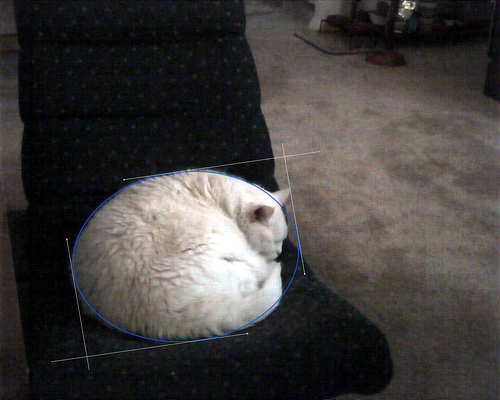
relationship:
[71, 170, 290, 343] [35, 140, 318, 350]
blue circle around cat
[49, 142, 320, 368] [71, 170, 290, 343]
lines drawn around blue circle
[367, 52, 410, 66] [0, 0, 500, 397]
dish on floor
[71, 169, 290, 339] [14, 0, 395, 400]
cat laying on black chair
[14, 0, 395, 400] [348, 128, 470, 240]
black chair sitting on ground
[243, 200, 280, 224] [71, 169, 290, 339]
ear on cat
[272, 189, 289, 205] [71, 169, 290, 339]
ear on cat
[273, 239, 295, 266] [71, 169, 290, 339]
nose on cat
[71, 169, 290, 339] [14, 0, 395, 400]
cat lying on black chair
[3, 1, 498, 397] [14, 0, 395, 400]
carpet next to black chair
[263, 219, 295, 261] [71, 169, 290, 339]
face on cat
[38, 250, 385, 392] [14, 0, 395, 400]
seat on black chair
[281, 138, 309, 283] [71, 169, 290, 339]
line next to cat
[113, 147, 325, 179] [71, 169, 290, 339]
line next to cat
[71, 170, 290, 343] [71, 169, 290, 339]
blue circle around cat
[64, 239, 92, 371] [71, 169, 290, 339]
line by cat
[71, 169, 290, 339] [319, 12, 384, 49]
cat in chair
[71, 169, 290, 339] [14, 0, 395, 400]
cat in black chair